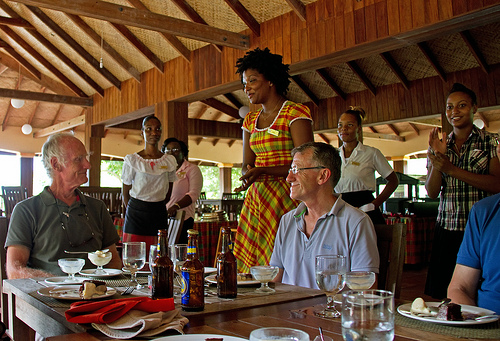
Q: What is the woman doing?
A: Talking to a man.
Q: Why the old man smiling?
A: He's happy.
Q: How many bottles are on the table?
A: Three.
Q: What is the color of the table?
A: Brown.